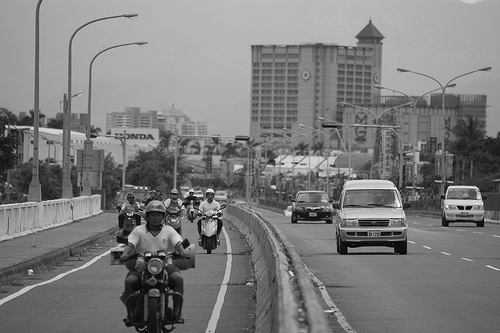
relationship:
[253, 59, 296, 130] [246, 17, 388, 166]
windows on house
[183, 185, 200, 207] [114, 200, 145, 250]
man on motorcycle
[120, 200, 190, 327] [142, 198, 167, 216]
man on helmet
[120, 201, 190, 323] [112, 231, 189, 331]
man on motorcycle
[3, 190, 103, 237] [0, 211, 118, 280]
railing on lane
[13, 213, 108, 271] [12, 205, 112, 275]
lane on sidewalk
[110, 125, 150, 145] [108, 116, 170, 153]
honda on building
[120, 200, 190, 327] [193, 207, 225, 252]
man on motorbike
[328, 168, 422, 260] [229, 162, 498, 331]
car on street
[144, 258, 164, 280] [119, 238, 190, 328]
headlight on bike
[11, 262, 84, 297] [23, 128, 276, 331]
line on road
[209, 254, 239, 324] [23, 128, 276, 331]
line on road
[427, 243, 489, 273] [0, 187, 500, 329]
lines on road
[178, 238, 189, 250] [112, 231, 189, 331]
mirror on motorcycle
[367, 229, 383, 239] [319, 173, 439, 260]
license plate on vehicle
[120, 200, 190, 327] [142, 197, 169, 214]
man wearing helmet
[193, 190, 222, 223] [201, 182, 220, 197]
man wearing helmet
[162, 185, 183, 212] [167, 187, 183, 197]
man wearing helmet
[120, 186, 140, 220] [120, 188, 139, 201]
man wearing helmet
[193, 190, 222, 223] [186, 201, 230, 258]
man riding motorcycle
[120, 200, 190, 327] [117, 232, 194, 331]
man riding motorcycle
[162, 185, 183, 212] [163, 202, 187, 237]
man riding bike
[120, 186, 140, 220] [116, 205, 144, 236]
man riding bike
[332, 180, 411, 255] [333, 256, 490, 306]
car driving down road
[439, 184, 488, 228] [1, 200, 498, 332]
vehicle driving down road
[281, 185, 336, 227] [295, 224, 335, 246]
black car driving down road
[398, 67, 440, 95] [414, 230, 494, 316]
light over road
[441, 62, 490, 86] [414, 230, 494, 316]
light over road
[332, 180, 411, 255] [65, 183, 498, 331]
car on a road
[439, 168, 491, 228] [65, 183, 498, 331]
vehicle on a road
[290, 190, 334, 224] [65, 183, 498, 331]
black car on a road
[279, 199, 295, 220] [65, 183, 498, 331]
vehicle on a road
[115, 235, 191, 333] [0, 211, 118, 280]
bike on a lane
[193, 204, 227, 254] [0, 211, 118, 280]
bike on a lane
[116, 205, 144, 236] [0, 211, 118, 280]
bike on a lane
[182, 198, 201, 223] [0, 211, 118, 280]
bike on a lane